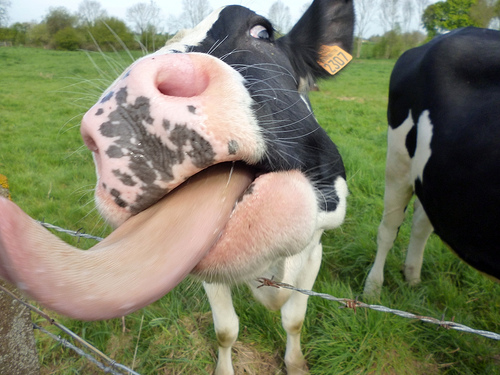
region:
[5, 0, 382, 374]
A cow with its tounge out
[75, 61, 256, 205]
A black and pink cow's nose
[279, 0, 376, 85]
A tagged ear on a cow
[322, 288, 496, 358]
Grey, rusting barbed wire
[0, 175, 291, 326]
A long, pink cow's tongue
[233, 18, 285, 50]
A cow's eye looking to its left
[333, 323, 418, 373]
Thick green and brown grass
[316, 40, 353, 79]
An orange tag with a number printed on it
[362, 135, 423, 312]
The back leg of a cow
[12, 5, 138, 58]
Thick trees on the edge of a pasture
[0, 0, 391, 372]
A cow sticking out its tongue.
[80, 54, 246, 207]
The cow's nose has spots of black pigmentation.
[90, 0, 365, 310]
The cow is black and white.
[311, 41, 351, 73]
There is an orange tag in the cow's ear.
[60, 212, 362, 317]
The cow's neck is above barbed wire.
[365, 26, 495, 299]
The back end of a black and white cow.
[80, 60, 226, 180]
The cow's nostrils are pink.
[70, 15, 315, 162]
The cow has white whiskers.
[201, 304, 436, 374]
The cows are standing on grass.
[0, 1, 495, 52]
There are trees and brush behind the cows.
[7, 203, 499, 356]
This is a wiremesh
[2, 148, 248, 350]
This is a tongue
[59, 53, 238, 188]
Nose of a cow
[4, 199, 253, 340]
Tongue of a cow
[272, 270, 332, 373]
Leg of a cow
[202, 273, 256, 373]
Leg of a cow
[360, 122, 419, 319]
Leg of a cow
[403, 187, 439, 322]
Leg of a cow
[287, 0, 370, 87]
This is an ear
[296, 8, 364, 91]
This is a name tag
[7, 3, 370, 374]
A cow in a field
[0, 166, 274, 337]
The tongue of a cow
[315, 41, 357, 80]
A tag in a cow's ear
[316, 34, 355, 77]
A tag that says 2307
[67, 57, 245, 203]
A close-up of a cow's nose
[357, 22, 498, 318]
The back half of a cow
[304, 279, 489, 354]
Barbed wire on a fence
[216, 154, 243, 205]
Slobber on a cow tongue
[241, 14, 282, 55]
The eye of a cow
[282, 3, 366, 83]
The ear of a cow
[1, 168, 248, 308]
the tongue of a cow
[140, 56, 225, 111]
the nose of a cow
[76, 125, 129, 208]
the nose of a cow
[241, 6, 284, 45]
the eye of a cow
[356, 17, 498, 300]
this is a cow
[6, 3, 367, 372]
this is a cow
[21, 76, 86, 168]
a patch of grass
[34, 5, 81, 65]
this is a tree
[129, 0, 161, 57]
this is a tree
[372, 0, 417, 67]
this is a tree